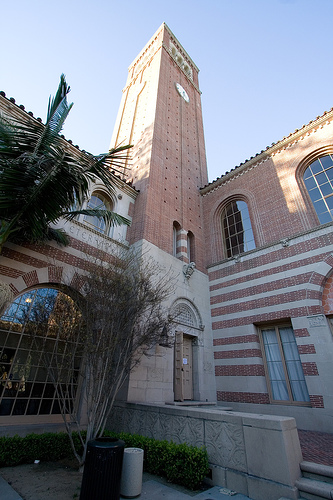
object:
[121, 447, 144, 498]
ash tray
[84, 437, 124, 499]
trash can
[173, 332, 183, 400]
door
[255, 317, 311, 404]
window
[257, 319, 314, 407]
trim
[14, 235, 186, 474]
tree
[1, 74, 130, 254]
palm tree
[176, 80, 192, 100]
clock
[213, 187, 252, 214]
half circle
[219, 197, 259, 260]
window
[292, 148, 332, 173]
half circle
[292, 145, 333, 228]
window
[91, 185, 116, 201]
half circle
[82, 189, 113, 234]
window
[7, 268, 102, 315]
half circle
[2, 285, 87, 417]
window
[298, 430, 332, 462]
sidewalk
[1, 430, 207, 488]
hedge row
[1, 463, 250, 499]
street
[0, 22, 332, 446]
building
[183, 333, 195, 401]
door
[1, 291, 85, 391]
reflection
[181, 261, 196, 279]
statue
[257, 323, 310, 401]
curtain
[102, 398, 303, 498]
wall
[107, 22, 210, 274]
tower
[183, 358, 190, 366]
paper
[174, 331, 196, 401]
doorway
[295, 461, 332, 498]
stairs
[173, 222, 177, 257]
window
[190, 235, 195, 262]
window